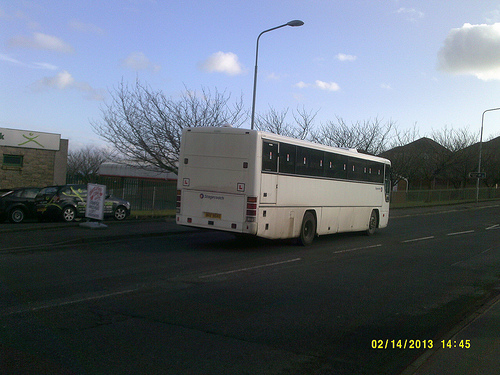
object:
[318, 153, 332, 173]
window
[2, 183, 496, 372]
street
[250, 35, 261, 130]
pole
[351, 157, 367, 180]
window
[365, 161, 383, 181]
window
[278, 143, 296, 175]
window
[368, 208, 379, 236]
wheel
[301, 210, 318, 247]
wheel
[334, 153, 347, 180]
window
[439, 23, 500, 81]
cloud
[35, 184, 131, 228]
hybrid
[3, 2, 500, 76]
sky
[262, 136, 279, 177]
window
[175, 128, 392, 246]
bus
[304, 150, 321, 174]
window